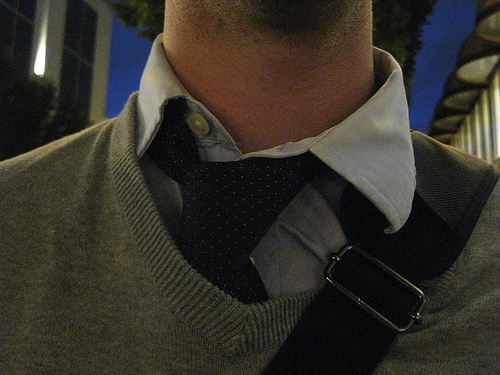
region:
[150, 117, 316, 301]
a crooked neck tie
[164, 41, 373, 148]
the neck of a man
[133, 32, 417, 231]
the collar of a shirt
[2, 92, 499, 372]
a gray sweater over the man's shirt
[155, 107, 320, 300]
a black tie with small dots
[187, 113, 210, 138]
a button on the shirt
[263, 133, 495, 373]
a black and grey strap on the man's shoulder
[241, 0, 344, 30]
the man's lower chin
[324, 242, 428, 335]
a black metal attachment for adjusting the strap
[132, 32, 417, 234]
the neck of a shirt on the man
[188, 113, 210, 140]
Button on collar.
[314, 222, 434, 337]
Strap lengthening buckle.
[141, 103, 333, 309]
Crooked blue and spotted tie.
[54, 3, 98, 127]
Four panel window.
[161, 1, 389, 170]
A mans neck.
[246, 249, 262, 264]
Edge of button peeking out from under tie.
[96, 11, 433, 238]
Crooked shirt collar.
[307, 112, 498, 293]
Shoulder pad on strap of bag.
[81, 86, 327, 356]
V-neck collar.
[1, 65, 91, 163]
Bush in the background.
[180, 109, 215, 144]
white button on collar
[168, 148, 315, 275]
knot in top of tie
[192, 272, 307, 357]
v neck of gray sweater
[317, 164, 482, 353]
black strap on shoulder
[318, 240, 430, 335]
metal buckle on strap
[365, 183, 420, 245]
curl on end of collar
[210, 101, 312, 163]
open collar on shirt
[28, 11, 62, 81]
light reflection on building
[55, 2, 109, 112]
window on side of building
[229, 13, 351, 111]
neck of white male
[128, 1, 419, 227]
A man's neck framed by a white collar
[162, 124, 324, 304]
Knot of a blue tie with white polk-a-dots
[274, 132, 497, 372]
Strap of a gym or laptop bag over a shoulder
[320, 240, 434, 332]
Metal buckle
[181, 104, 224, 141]
Button on a shirt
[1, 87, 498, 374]
Grey v-neck sweater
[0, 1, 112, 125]
Two windows with white frames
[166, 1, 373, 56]
Five o'clock shadow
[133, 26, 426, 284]
White shirt with an unbuttoned collar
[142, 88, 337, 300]
Skewed tie around a man's neck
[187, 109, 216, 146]
button on collar of shirt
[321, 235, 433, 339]
silver metal clasp on strap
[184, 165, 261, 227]
polka dot pattern on neck tie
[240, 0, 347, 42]
stubble on chin of man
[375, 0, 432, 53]
tree with green leaves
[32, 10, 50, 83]
light on side of building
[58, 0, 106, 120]
large window on side of building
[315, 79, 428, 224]
collar of white shirt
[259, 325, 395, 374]
black strap on front of man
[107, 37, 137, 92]
clear blue night sky